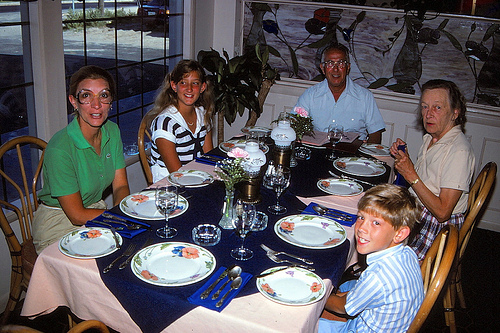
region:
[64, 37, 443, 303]
A family having dinner.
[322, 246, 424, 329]
The boy has on a striped shirt.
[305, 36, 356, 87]
The man is wearing glasses.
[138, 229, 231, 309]
The plates have flowers around the edge.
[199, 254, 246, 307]
The napkin is blue.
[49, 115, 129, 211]
the lady is wearing a green shirt.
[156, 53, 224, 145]
The girl has long blonde hair.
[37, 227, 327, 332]
The table cloth is pink.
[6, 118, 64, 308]
The chairs are made out of wood.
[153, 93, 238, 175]
The girl has on a blue and white striped shirt.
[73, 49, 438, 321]
Family dinner favorite restaurant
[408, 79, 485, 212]
Grandmother not want pic taken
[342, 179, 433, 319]
Boy cracks good smile camera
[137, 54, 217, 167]
Daughter looks smiles mother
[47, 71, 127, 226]
Big glasses serious face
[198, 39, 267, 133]
Floor plant resides corner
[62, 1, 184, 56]
Snow shown through window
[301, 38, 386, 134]
Man blue shirt tanned face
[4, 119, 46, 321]
Seating provided wicker chairs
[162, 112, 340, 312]
Attractive dinnerware pink flowers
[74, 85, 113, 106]
Very large eye glasses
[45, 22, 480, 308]
Family sitting down for a fancy meal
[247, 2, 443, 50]
Part of a drawing on the back wall.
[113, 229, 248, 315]
Fancy dinner set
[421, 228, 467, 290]
Back of a dinner chair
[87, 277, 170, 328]
Pink and blue tablecloth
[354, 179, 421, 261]
boy with cheesey smile sporting an 80s style haircut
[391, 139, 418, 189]
Hands of an elderly person holding a napkin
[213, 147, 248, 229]
A rose in a glass vase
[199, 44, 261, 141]
Tree in the corner of the room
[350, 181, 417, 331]
young boy on bottom right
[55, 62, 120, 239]
woman wearing glasses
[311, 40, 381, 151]
older man wearing glasses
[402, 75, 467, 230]
older woman looking at camera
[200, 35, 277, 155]
standing plant in the back corner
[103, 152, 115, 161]
small logo on green shirt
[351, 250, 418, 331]
blue and white striped color shirt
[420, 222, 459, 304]
back of wooden chair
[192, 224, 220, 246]
clear glass ash tray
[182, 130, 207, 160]
tie on girls top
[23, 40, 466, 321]
a group of people sitting around a dining table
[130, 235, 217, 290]
a floral print plate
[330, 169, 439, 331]
a young boy smiling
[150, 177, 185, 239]
an empty wine goblet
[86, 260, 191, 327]
the end of a blue table runner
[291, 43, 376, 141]
a man in a blue shirt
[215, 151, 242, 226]
a vase with flowers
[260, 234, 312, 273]
two forks next to a plate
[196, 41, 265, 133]
an artificial tree in the corner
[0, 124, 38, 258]
the back of a wooden chair